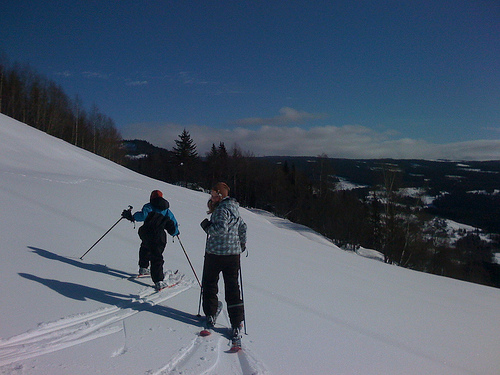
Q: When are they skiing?
A: Daytime.